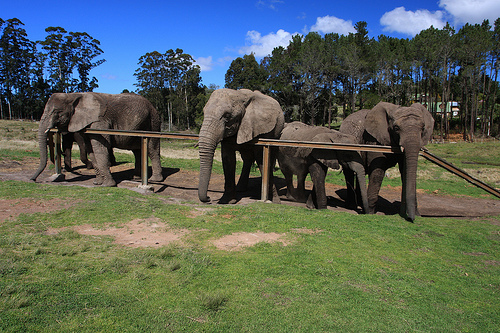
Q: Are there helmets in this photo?
A: No, there are no helmets.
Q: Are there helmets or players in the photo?
A: No, there are no helmets or players.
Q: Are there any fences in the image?
A: Yes, there is a fence.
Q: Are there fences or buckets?
A: Yes, there is a fence.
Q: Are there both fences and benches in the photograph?
A: No, there is a fence but no benches.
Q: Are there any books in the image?
A: No, there are no books.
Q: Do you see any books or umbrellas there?
A: No, there are no books or umbrellas.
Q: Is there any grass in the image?
A: Yes, there is grass.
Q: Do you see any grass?
A: Yes, there is grass.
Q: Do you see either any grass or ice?
A: Yes, there is grass.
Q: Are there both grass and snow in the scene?
A: No, there is grass but no snow.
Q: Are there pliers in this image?
A: No, there are no pliers.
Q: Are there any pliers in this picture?
A: No, there are no pliers.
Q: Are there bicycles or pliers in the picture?
A: No, there are no pliers or bicycles.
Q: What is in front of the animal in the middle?
A: The grass is in front of the animal.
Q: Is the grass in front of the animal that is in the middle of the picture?
A: Yes, the grass is in front of the animal.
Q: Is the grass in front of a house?
A: No, the grass is in front of the animal.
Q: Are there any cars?
A: No, there are no cars.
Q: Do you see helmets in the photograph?
A: No, there are no helmets.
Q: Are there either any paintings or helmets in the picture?
A: No, there are no helmets or paintings.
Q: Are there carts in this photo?
A: No, there are no carts.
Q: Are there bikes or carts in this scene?
A: No, there are no carts or bikes.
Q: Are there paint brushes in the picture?
A: No, there are no paint brushes.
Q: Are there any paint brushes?
A: No, there are no paint brushes.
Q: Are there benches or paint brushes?
A: No, there are no paint brushes or benches.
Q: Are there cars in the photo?
A: No, there are no cars.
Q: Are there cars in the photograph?
A: No, there are no cars.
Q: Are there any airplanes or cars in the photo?
A: No, there are no cars or airplanes.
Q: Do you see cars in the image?
A: No, there are no cars.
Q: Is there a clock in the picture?
A: No, there are no clocks.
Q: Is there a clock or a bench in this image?
A: No, there are no clocks or benches.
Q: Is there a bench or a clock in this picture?
A: No, there are no clocks or benches.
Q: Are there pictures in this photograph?
A: No, there are no pictures.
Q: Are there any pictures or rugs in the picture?
A: No, there are no pictures or rugs.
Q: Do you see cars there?
A: No, there are no cars.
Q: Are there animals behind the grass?
A: Yes, there is an animal behind the grass.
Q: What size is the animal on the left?
A: The animal is large.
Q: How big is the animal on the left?
A: The animal is large.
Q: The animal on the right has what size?
A: The animal is large.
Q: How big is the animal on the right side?
A: The animal is large.